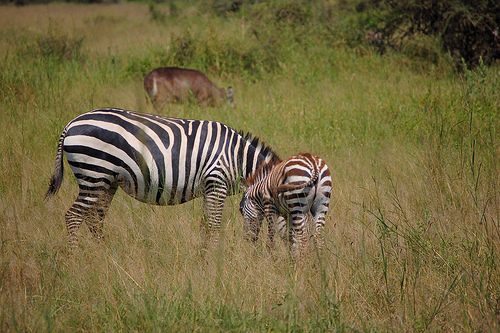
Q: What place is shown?
A: It is a plain.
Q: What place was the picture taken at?
A: It was taken at the plain.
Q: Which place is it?
A: It is a plain.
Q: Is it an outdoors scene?
A: Yes, it is outdoors.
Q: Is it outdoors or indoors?
A: It is outdoors.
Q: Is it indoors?
A: No, it is outdoors.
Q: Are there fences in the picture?
A: No, there are no fences.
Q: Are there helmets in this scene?
A: No, there are no helmets.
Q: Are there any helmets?
A: No, there are no helmets.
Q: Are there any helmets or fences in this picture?
A: No, there are no helmets or fences.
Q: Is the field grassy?
A: Yes, the field is grassy.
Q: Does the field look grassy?
A: Yes, the field is grassy.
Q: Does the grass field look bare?
A: No, the field is grassy.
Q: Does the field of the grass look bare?
A: No, the field is grassy.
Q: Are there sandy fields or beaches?
A: No, there is a field but it is grassy.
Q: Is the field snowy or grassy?
A: The field is grassy.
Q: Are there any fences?
A: No, there are no fences.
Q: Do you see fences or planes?
A: No, there are no fences or planes.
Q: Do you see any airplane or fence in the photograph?
A: No, there are no fences or airplanes.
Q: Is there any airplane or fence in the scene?
A: No, there are no fences or airplanes.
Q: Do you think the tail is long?
A: Yes, the tail is long.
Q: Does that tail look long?
A: Yes, the tail is long.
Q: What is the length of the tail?
A: The tail is long.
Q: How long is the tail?
A: The tail is long.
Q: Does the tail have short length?
A: No, the tail is long.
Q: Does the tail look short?
A: No, the tail is long.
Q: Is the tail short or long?
A: The tail is long.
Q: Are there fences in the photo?
A: No, there are no fences.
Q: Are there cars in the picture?
A: No, there are no cars.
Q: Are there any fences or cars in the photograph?
A: No, there are no cars or fences.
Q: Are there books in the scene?
A: No, there are no books.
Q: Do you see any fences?
A: No, there are no fences.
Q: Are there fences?
A: No, there are no fences.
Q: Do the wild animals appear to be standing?
A: Yes, the animals are standing.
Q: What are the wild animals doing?
A: The animals are standing.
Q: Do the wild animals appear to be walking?
A: No, the animals are standing.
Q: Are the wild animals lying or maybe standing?
A: The animals are standing.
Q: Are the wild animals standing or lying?
A: The animals are standing.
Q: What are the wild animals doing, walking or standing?
A: The animals are standing.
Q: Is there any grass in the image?
A: Yes, there is grass.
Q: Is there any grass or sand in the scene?
A: Yes, there is grass.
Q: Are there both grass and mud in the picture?
A: No, there is grass but no mud.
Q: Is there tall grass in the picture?
A: Yes, there is tall grass.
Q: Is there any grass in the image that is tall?
A: Yes, there is grass that is tall.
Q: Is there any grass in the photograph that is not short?
A: Yes, there is tall grass.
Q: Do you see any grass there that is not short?
A: Yes, there is tall grass.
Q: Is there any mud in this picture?
A: No, there is no mud.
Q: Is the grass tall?
A: Yes, the grass is tall.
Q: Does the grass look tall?
A: Yes, the grass is tall.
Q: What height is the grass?
A: The grass is tall.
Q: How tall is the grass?
A: The grass is tall.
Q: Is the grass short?
A: No, the grass is tall.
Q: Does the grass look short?
A: No, the grass is tall.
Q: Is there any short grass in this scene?
A: No, there is grass but it is tall.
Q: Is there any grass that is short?
A: No, there is grass but it is tall.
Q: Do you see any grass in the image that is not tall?
A: No, there is grass but it is tall.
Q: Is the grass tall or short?
A: The grass is tall.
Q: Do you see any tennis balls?
A: No, there are no tennis balls.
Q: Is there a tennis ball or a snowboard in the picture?
A: No, there are no tennis balls or snowboards.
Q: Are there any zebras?
A: Yes, there is a zebra.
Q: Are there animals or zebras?
A: Yes, there is a zebra.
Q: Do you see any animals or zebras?
A: Yes, there is a zebra.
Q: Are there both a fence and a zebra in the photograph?
A: No, there is a zebra but no fences.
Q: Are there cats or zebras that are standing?
A: Yes, the zebra is standing.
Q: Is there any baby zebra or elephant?
A: Yes, there is a baby zebra.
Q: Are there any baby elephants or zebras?
A: Yes, there is a baby zebra.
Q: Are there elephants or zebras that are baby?
A: Yes, the zebra is a baby.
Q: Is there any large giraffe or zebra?
A: Yes, there is a large zebra.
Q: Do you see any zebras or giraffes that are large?
A: Yes, the zebra is large.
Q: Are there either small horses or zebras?
A: Yes, there is a small zebra.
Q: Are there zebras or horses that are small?
A: Yes, the zebra is small.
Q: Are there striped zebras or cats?
A: Yes, there is a striped zebra.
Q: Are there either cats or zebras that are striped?
A: Yes, the zebra is striped.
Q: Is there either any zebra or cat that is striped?
A: Yes, the zebra is striped.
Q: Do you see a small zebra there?
A: Yes, there is a small zebra.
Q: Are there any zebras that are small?
A: Yes, there is a zebra that is small.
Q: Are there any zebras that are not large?
A: Yes, there is a small zebra.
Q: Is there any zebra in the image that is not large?
A: Yes, there is a small zebra.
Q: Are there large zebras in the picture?
A: Yes, there is a large zebra.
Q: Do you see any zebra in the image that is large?
A: Yes, there is a zebra that is large.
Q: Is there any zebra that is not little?
A: Yes, there is a large zebra.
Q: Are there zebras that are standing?
A: Yes, there is a zebra that is standing.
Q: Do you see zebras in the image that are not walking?
A: Yes, there is a zebra that is standing .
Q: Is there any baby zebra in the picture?
A: Yes, there is a baby zebra.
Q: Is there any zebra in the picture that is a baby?
A: Yes, there is a zebra that is a baby.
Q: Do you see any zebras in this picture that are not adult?
A: Yes, there is an baby zebra.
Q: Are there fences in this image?
A: No, there are no fences.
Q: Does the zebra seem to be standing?
A: Yes, the zebra is standing.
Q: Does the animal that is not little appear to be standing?
A: Yes, the zebra is standing.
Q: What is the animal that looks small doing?
A: The zebra is standing.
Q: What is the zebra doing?
A: The zebra is standing.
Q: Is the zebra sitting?
A: No, the zebra is standing.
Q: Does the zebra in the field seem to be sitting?
A: No, the zebra is standing.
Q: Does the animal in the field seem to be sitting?
A: No, the zebra is standing.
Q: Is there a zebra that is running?
A: No, there is a zebra but it is standing.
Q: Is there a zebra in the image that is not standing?
A: No, there is a zebra but it is standing.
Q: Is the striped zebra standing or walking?
A: The zebra is standing.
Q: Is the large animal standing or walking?
A: The zebra is standing.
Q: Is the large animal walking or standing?
A: The zebra is standing.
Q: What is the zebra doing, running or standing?
A: The zebra is standing.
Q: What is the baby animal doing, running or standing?
A: The zebra is standing.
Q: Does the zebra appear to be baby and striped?
A: Yes, the zebra is a baby and striped.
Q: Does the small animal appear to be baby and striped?
A: Yes, the zebra is a baby and striped.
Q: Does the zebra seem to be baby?
A: Yes, the zebra is a baby.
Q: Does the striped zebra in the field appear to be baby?
A: Yes, the zebra is a baby.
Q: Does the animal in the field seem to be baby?
A: Yes, the zebra is a baby.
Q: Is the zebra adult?
A: No, the zebra is a baby.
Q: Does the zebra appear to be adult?
A: No, the zebra is a baby.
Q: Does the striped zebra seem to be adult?
A: No, the zebra is a baby.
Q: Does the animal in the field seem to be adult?
A: No, the zebra is a baby.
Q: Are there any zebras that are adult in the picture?
A: No, there is a zebra but it is a baby.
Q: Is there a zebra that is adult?
A: No, there is a zebra but it is a baby.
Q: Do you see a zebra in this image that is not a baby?
A: No, there is a zebra but it is a baby.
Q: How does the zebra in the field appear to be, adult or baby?
A: The zebra is a baby.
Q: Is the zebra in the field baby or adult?
A: The zebra is a baby.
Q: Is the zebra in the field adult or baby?
A: The zebra is a baby.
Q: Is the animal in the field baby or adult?
A: The zebra is a baby.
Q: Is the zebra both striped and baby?
A: Yes, the zebra is striped and baby.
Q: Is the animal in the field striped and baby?
A: Yes, the zebra is striped and baby.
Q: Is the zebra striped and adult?
A: No, the zebra is striped but baby.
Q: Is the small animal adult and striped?
A: No, the zebra is striped but baby.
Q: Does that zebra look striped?
A: Yes, the zebra is striped.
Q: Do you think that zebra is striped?
A: Yes, the zebra is striped.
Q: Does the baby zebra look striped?
A: Yes, the zebra is striped.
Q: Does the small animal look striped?
A: Yes, the zebra is striped.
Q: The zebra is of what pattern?
A: The zebra is striped.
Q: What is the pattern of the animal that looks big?
A: The zebra is striped.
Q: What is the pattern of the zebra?
A: The zebra is striped.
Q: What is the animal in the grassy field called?
A: The animal is a zebra.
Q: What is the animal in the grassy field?
A: The animal is a zebra.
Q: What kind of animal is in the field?
A: The animal is a zebra.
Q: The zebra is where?
A: The zebra is in the field.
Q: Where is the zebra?
A: The zebra is in the field.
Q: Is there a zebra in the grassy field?
A: Yes, there is a zebra in the field.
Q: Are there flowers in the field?
A: No, there is a zebra in the field.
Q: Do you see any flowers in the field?
A: No, there is a zebra in the field.